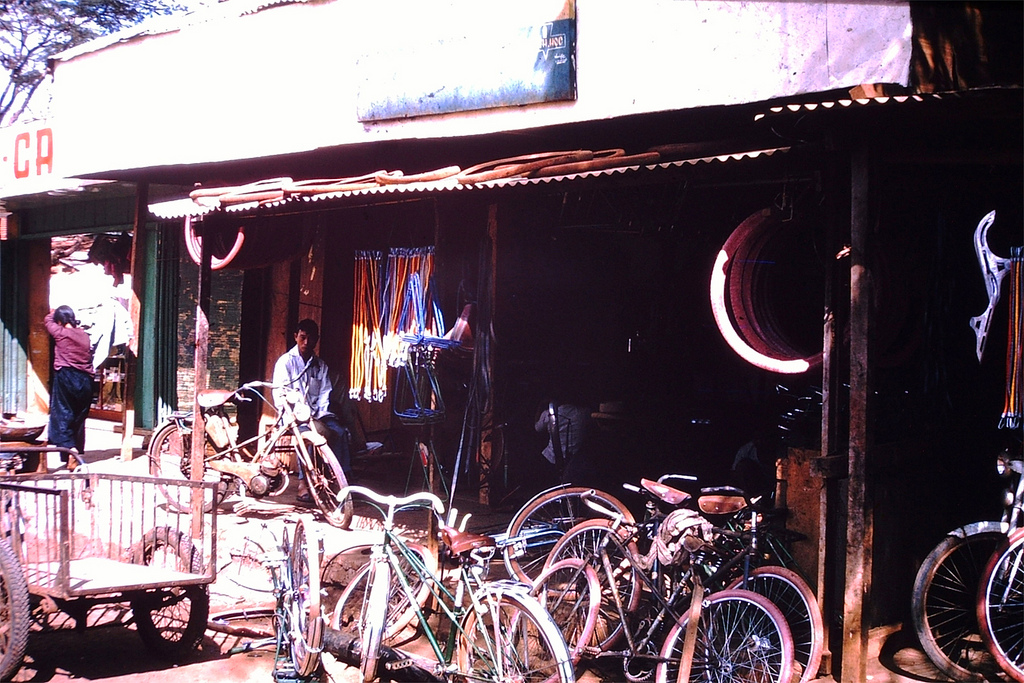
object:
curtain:
[350, 249, 386, 403]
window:
[350, 246, 448, 402]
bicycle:
[503, 474, 824, 682]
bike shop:
[58, 90, 1021, 683]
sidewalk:
[20, 387, 414, 634]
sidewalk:
[124, 359, 356, 604]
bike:
[145, 356, 351, 531]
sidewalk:
[0, 420, 435, 651]